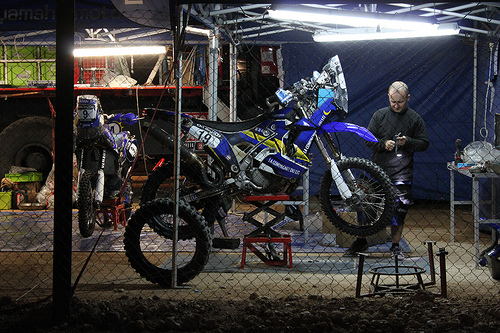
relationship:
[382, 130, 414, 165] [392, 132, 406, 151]
light in man's hand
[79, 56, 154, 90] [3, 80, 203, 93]
supplies sitting on shelf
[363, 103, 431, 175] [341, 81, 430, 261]
shirt on man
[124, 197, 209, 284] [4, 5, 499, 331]
tire leaning against fence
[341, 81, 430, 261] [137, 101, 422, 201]
man repairing motorcycle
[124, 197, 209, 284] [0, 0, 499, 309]
tire leaning against chainlink fence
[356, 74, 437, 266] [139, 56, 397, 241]
man on bike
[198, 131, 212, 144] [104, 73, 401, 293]
19 on bike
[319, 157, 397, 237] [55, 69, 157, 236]
front tire on bike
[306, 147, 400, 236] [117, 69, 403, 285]
front tire of motorcycle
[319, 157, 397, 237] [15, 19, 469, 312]
front tire on picture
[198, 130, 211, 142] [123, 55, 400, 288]
19 on motorcycle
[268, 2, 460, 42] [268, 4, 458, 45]
fluorescent light on ceiling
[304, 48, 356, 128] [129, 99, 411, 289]
bug shield on bike